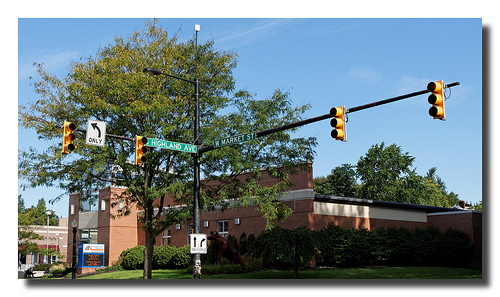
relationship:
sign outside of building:
[73, 237, 110, 269] [53, 150, 419, 284]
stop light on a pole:
[62, 122, 75, 153] [192, 79, 204, 277]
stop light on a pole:
[132, 133, 149, 164] [71, 127, 141, 141]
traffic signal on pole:
[328, 105, 346, 138] [200, 80, 460, 148]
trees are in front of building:
[19, 17, 320, 279] [100, 167, 490, 260]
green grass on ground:
[79, 262, 484, 287] [13, 241, 485, 293]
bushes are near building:
[117, 239, 198, 269] [90, 177, 493, 277]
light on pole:
[312, 97, 374, 154] [200, 80, 460, 148]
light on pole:
[426, 77, 447, 122] [202, 80, 461, 155]